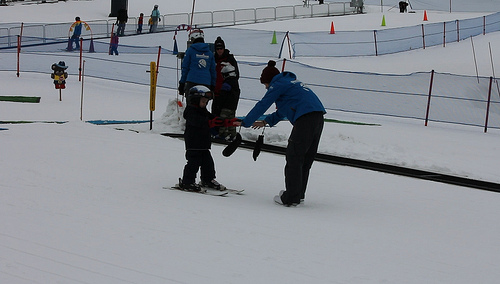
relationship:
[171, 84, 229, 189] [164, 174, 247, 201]
child on skis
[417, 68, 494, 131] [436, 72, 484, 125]
poles on fence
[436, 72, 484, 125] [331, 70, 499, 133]
fence in row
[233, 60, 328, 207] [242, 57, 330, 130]
people bending over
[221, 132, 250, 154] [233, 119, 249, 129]
glove from wrist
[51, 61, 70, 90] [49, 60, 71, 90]
bear of bear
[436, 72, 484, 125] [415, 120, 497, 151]
fence on snow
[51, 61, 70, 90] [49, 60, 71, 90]
bear of animal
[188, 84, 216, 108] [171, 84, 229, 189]
helmet on child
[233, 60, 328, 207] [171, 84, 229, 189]
people helping child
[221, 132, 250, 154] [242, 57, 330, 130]
glove on jacket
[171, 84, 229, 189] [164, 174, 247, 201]
boy on skis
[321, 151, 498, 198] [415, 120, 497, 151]
railing in snow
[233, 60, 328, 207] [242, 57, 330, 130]
people in jacket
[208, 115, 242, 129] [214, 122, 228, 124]
gloves are black and red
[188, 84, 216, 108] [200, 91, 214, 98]
helmet and googles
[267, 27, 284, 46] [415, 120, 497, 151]
cone in snow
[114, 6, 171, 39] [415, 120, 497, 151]
people on snow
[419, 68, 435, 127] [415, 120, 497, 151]
pole in snow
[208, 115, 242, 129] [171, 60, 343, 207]
gloves hanging between people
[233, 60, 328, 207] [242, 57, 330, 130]
people with coat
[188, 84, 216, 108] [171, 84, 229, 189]
helmet on boy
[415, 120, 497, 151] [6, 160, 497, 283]
snow on ground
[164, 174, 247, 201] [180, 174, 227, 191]
skis on feet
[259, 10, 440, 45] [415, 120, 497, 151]
cones in snow